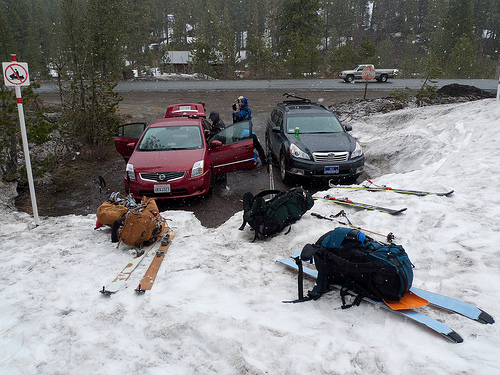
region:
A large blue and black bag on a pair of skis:
[296, 223, 419, 303]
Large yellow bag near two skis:
[95, 195, 161, 251]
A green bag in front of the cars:
[247, 185, 312, 227]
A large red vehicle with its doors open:
[110, 100, 250, 199]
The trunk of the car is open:
[158, 96, 217, 128]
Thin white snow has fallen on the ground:
[174, 295, 309, 367]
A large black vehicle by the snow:
[267, 98, 377, 190]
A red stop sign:
[354, 62, 385, 102]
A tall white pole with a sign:
[3, 53, 68, 223]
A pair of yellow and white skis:
[103, 230, 183, 302]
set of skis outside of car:
[104, 251, 204, 307]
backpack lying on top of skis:
[312, 194, 449, 328]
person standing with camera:
[225, 94, 267, 114]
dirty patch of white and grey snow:
[367, 118, 447, 160]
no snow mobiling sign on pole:
[6, 63, 47, 100]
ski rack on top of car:
[280, 83, 334, 112]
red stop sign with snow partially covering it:
[361, 69, 386, 93]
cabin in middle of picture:
[169, 30, 253, 85]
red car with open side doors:
[101, 119, 277, 171]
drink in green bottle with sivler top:
[283, 120, 316, 139]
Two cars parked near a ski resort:
[80, 90, 490, 370]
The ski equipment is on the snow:
[75, 80, 495, 360]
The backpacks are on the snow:
[85, 75, 480, 360]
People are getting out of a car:
[75, 65, 440, 305]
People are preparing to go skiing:
[60, 55, 460, 335]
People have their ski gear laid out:
[60, 86, 495, 346]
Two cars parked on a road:
[70, 65, 440, 370]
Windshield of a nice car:
[140, 121, 200, 146]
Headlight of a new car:
[186, 156, 201, 172]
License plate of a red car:
[147, 180, 172, 191]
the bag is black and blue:
[312, 229, 407, 284]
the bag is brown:
[121, 204, 162, 237]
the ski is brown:
[142, 256, 166, 295]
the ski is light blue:
[432, 289, 470, 319]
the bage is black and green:
[254, 199, 309, 226]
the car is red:
[153, 155, 188, 166]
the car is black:
[304, 134, 342, 154]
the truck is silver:
[348, 69, 371, 83]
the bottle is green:
[288, 122, 306, 140]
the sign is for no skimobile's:
[2, 52, 38, 95]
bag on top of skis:
[295, 226, 415, 309]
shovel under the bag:
[374, 279, 427, 315]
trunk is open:
[158, 99, 208, 122]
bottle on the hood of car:
[290, 124, 304, 137]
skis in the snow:
[319, 173, 444, 221]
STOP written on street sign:
[361, 59, 377, 105]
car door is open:
[107, 115, 158, 165]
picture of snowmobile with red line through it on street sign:
[7, 60, 33, 89]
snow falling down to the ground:
[401, 18, 467, 72]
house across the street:
[159, 43, 243, 76]